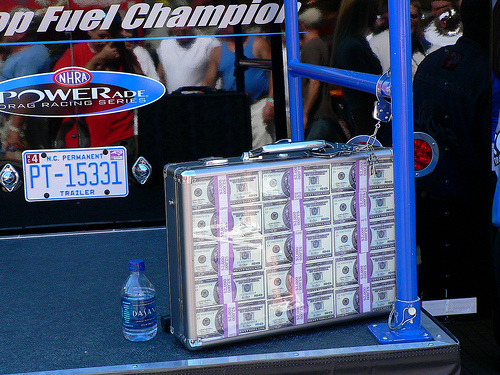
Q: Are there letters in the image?
A: Yes, there are letters.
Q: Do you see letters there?
A: Yes, there are letters.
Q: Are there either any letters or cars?
A: Yes, there are letters.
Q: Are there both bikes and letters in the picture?
A: No, there are letters but no bikes.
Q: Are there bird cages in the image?
A: No, there are no bird cages.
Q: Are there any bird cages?
A: No, there are no bird cages.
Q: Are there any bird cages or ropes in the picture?
A: No, there are no bird cages or ropes.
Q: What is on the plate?
A: The letters are on the plate.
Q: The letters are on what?
A: The letters are on the plate.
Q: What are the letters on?
A: The letters are on the plate.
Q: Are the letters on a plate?
A: Yes, the letters are on a plate.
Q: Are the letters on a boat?
A: No, the letters are on a plate.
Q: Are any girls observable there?
A: No, there are no girls.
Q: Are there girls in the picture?
A: No, there are no girls.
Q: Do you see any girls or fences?
A: No, there are no girls or fences.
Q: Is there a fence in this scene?
A: No, there are no fences.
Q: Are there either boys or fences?
A: No, there are no fences or boys.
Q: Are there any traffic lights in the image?
A: No, there are no traffic lights.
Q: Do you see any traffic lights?
A: No, there are no traffic lights.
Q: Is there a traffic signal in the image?
A: No, there are no traffic lights.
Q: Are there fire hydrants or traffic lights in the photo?
A: No, there are no traffic lights or fire hydrants.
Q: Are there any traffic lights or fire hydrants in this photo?
A: No, there are no traffic lights or fire hydrants.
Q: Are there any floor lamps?
A: No, there are no floor lamps.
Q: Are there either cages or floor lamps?
A: No, there are no floor lamps or cages.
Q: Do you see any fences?
A: No, there are no fences.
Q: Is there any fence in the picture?
A: No, there are no fences.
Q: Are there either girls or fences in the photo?
A: No, there are no fences or girls.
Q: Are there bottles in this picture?
A: Yes, there is a bottle.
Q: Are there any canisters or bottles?
A: Yes, there is a bottle.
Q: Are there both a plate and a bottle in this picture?
A: Yes, there are both a bottle and a plate.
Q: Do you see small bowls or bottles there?
A: Yes, there is a small bottle.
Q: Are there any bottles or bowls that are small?
A: Yes, the bottle is small.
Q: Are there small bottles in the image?
A: Yes, there is a small bottle.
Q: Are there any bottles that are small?
A: Yes, there is a bottle that is small.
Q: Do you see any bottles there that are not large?
A: Yes, there is a small bottle.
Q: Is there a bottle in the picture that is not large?
A: Yes, there is a small bottle.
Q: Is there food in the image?
A: No, there is no food.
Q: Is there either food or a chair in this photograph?
A: No, there are no food or chairs.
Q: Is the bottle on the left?
A: Yes, the bottle is on the left of the image.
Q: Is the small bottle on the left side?
A: Yes, the bottle is on the left of the image.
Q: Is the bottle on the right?
A: No, the bottle is on the left of the image.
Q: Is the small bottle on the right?
A: No, the bottle is on the left of the image.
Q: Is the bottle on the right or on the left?
A: The bottle is on the left of the image.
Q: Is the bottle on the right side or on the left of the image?
A: The bottle is on the left of the image.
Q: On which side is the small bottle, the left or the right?
A: The bottle is on the left of the image.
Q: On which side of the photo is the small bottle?
A: The bottle is on the left of the image.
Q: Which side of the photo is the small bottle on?
A: The bottle is on the left of the image.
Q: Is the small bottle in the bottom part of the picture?
A: Yes, the bottle is in the bottom of the image.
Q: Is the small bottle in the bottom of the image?
A: Yes, the bottle is in the bottom of the image.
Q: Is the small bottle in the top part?
A: No, the bottle is in the bottom of the image.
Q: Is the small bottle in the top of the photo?
A: No, the bottle is in the bottom of the image.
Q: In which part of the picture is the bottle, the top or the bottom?
A: The bottle is in the bottom of the image.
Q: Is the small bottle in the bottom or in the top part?
A: The bottle is in the bottom of the image.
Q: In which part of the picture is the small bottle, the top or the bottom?
A: The bottle is in the bottom of the image.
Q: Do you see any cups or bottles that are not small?
A: No, there is a bottle but it is small.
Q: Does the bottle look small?
A: Yes, the bottle is small.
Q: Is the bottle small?
A: Yes, the bottle is small.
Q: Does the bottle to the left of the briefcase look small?
A: Yes, the bottle is small.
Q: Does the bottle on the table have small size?
A: Yes, the bottle is small.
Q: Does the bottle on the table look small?
A: Yes, the bottle is small.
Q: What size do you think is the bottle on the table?
A: The bottle is small.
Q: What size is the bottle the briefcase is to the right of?
A: The bottle is small.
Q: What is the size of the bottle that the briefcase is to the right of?
A: The bottle is small.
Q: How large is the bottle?
A: The bottle is small.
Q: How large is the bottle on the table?
A: The bottle is small.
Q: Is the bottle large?
A: No, the bottle is small.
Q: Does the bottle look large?
A: No, the bottle is small.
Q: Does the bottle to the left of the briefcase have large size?
A: No, the bottle is small.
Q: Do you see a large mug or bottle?
A: No, there is a bottle but it is small.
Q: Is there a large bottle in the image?
A: No, there is a bottle but it is small.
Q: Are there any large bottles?
A: No, there is a bottle but it is small.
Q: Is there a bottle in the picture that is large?
A: No, there is a bottle but it is small.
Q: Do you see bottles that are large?
A: No, there is a bottle but it is small.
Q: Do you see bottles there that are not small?
A: No, there is a bottle but it is small.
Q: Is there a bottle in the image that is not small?
A: No, there is a bottle but it is small.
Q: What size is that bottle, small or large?
A: The bottle is small.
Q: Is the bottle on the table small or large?
A: The bottle is small.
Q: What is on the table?
A: The bottle is on the table.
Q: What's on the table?
A: The bottle is on the table.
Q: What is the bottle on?
A: The bottle is on the table.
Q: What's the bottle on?
A: The bottle is on the table.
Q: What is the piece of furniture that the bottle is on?
A: The piece of furniture is a table.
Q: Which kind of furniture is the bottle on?
A: The bottle is on the table.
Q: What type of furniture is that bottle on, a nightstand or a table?
A: The bottle is on a table.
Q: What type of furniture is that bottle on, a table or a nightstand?
A: The bottle is on a table.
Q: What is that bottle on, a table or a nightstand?
A: The bottle is on a table.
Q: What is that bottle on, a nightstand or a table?
A: The bottle is on a table.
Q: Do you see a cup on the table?
A: No, there is a bottle on the table.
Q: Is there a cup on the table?
A: No, there is a bottle on the table.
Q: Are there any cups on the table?
A: No, there is a bottle on the table.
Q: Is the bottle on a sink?
A: No, the bottle is on the table.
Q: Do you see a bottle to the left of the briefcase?
A: Yes, there is a bottle to the left of the briefcase.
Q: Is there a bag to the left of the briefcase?
A: No, there is a bottle to the left of the briefcase.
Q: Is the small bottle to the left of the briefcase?
A: Yes, the bottle is to the left of the briefcase.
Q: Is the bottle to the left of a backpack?
A: No, the bottle is to the left of the briefcase.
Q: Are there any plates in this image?
A: Yes, there is a plate.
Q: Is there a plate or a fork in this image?
A: Yes, there is a plate.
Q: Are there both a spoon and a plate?
A: No, there is a plate but no spoons.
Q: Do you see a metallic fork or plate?
A: Yes, there is a metal plate.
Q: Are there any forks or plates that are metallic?
A: Yes, the plate is metallic.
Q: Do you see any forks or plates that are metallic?
A: Yes, the plate is metallic.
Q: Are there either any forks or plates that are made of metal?
A: Yes, the plate is made of metal.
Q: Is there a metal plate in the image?
A: Yes, there is a metal plate.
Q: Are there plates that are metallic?
A: Yes, there is a plate that is metallic.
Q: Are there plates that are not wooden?
A: Yes, there is a metallic plate.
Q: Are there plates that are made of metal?
A: Yes, there is a plate that is made of metal.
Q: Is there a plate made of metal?
A: Yes, there is a plate that is made of metal.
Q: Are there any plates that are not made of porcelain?
A: Yes, there is a plate that is made of metal.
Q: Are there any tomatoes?
A: No, there are no tomatoes.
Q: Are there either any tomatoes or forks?
A: No, there are no tomatoes or forks.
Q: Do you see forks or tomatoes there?
A: No, there are no tomatoes or forks.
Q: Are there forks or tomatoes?
A: No, there are no tomatoes or forks.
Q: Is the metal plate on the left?
A: Yes, the plate is on the left of the image.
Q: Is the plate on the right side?
A: No, the plate is on the left of the image.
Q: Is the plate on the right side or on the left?
A: The plate is on the left of the image.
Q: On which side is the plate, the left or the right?
A: The plate is on the left of the image.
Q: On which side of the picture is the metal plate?
A: The plate is on the left of the image.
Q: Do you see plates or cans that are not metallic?
A: No, there is a plate but it is metallic.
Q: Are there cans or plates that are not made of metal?
A: No, there is a plate but it is made of metal.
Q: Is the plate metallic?
A: Yes, the plate is metallic.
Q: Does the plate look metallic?
A: Yes, the plate is metallic.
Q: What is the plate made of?
A: The plate is made of metal.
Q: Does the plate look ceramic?
A: No, the plate is metallic.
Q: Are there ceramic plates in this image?
A: No, there is a plate but it is metallic.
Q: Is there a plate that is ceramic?
A: No, there is a plate but it is metallic.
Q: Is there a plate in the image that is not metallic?
A: No, there is a plate but it is metallic.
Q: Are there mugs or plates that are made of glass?
A: No, there is a plate but it is made of metal.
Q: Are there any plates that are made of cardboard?
A: No, there is a plate but it is made of metal.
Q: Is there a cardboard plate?
A: No, there is a plate but it is made of metal.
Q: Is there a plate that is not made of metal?
A: No, there is a plate but it is made of metal.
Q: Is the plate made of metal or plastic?
A: The plate is made of metal.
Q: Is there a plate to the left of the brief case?
A: Yes, there is a plate to the left of the brief case.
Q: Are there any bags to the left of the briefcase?
A: No, there is a plate to the left of the briefcase.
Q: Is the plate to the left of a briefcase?
A: Yes, the plate is to the left of a briefcase.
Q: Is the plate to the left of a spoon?
A: No, the plate is to the left of a briefcase.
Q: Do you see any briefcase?
A: Yes, there is a briefcase.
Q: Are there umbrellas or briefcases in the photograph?
A: Yes, there is a briefcase.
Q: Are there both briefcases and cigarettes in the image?
A: No, there is a briefcase but no cigarettes.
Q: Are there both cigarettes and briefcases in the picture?
A: No, there is a briefcase but no cigarettes.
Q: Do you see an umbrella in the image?
A: No, there are no umbrellas.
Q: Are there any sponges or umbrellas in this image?
A: No, there are no umbrellas or sponges.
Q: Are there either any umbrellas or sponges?
A: No, there are no umbrellas or sponges.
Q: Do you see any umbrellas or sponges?
A: No, there are no umbrellas or sponges.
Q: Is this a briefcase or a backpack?
A: This is a briefcase.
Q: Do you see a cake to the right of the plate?
A: No, there is a briefcase to the right of the plate.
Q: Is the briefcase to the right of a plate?
A: Yes, the briefcase is to the right of a plate.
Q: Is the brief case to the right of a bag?
A: No, the brief case is to the right of a plate.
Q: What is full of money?
A: The briefcase is full of money.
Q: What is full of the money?
A: The briefcase is full of money.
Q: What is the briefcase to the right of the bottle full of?
A: The brief case is full of money.